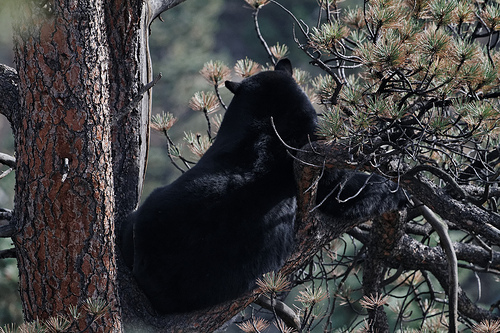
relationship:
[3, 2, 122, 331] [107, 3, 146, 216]
tree close to tree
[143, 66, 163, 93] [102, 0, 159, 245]
limb coming off of tree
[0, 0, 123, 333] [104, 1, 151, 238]
tree trunks close to trunk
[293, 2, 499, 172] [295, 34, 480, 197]
leaves on limbs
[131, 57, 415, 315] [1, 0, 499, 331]
bear in tree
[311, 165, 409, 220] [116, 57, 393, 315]
leg on bear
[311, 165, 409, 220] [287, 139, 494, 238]
leg on limb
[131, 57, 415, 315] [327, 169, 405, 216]
bear has arm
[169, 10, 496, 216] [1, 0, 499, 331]
needles on tree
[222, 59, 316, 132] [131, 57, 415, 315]
head on bear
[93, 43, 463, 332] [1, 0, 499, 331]
bear in tree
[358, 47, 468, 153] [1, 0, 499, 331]
needles on tree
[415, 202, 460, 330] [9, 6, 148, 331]
limb on tree